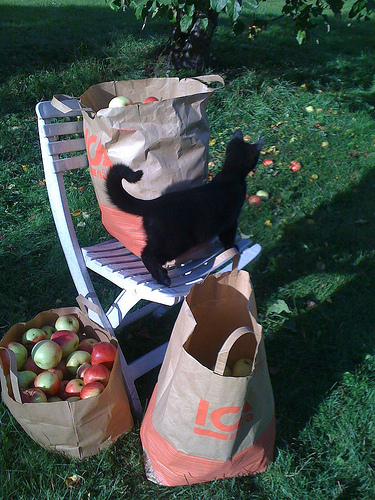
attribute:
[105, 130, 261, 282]
cat — black, curious, standing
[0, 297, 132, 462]
sack — full, brown, filled, paper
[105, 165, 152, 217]
tail — black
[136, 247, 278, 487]
sack — brown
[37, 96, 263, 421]
chair — white, wooden, plastic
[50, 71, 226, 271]
sack — brown, filled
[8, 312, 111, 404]
apples — green, red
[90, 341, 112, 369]
apple — red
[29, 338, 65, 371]
apple — green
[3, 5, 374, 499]
grass — green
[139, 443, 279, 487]
stripe — orange